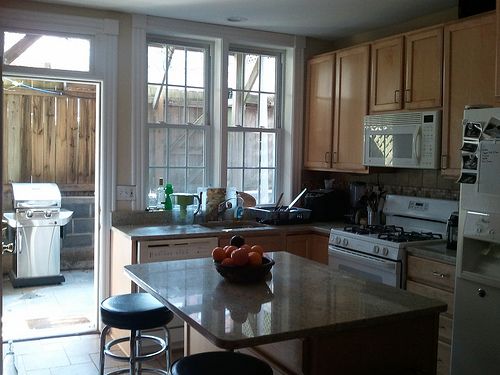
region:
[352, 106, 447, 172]
microwave above a range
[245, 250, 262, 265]
fruit in a bowl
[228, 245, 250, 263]
fruit in a bowl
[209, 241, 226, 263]
fruit in a bowl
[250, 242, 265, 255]
fruit in a bowl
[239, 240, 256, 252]
fruit in a bowl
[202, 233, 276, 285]
bowl of fruit on table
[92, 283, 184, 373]
stool in the kitchen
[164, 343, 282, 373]
stool in the kitchen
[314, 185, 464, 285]
white range in a kitchen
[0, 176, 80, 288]
stainless steep outdoor grill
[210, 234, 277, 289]
kitchen counter center piece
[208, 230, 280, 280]
fruit bowl on kitchen island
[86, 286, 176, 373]
black cushioned kitchen stool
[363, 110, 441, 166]
white overhead microwave oven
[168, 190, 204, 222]
green brita water pitcher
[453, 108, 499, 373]
white refrigerator with icemaker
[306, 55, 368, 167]
light brown wooden cabinets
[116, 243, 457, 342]
granit island counter top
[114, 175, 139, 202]
white plate kitchen switch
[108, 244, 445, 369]
counter on island in kitchen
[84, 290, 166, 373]
bar stool at counter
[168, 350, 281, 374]
seat of a stool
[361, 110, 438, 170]
microwave in the kitchen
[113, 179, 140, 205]
electrical control panel on wall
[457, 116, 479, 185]
pictures on the refrigerator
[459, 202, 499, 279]
ice maker and dispenser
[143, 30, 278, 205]
window in the kitchen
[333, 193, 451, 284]
oven in the kitchen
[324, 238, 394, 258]
knobs on the oven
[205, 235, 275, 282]
fruit bowl on kitchen counter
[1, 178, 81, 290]
stainless steel grill outside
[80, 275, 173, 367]
round, leather bar stool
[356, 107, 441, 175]
an over-the-counter white microwave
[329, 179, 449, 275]
gas oven and range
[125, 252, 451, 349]
an island bar in the middle of the kitchen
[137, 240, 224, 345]
a white dishwasher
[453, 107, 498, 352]
a white side-by-side refigerator/freezer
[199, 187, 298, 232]
a kitchen sink facing the window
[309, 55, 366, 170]
wood kitchen cabinets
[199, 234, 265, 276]
The fruit is in the basket.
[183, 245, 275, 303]
The basket is on the table.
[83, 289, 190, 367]
The stool is black.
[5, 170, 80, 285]
The grill is silver.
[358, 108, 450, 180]
The microwave is white.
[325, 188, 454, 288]
The stove is white.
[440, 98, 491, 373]
The fridge is white.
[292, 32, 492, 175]
The cabinets are brown.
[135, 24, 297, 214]
The windows are open.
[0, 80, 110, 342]
The door is open.